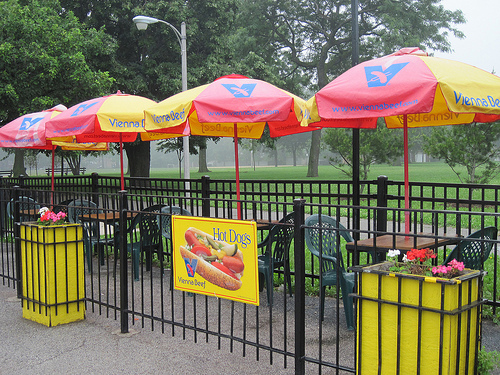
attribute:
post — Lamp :
[129, 12, 199, 210]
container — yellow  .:
[345, 269, 482, 362]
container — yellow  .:
[349, 264, 484, 371]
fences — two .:
[4, 169, 484, 359]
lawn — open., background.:
[2, 161, 482, 216]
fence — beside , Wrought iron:
[5, 173, 484, 371]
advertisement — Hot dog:
[164, 207, 264, 312]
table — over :
[11, 199, 475, 327]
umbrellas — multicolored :
[3, 50, 479, 247]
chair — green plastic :
[306, 215, 364, 333]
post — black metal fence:
[6, 173, 484, 364]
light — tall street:
[131, 7, 203, 218]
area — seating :
[15, 170, 484, 289]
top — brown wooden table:
[25, 214, 456, 254]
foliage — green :
[4, 1, 473, 104]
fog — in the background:
[42, 131, 363, 170]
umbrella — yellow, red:
[0, 81, 169, 166]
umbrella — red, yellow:
[35, 82, 196, 151]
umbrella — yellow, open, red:
[132, 60, 322, 141]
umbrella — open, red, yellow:
[311, 33, 484, 146]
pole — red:
[394, 109, 416, 236]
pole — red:
[229, 119, 249, 222]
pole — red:
[106, 123, 130, 193]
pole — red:
[40, 145, 60, 196]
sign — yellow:
[168, 208, 264, 306]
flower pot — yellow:
[350, 258, 483, 371]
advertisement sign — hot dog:
[164, 207, 265, 307]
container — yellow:
[14, 213, 84, 323]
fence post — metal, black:
[288, 195, 315, 373]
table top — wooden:
[82, 205, 150, 229]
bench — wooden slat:
[37, 163, 86, 179]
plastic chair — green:
[302, 206, 361, 331]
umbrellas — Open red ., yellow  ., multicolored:
[0, 37, 474, 235]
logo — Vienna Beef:
[177, 254, 197, 282]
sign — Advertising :
[162, 204, 268, 310]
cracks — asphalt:
[6, 311, 110, 365]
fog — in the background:
[80, 120, 288, 165]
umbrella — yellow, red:
[313, 40, 483, 154]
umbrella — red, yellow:
[124, 66, 316, 153]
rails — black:
[250, 194, 346, 372]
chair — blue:
[97, 202, 182, 279]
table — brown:
[71, 198, 151, 265]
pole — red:
[388, 105, 423, 248]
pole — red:
[39, 143, 66, 216]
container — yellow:
[352, 261, 497, 359]